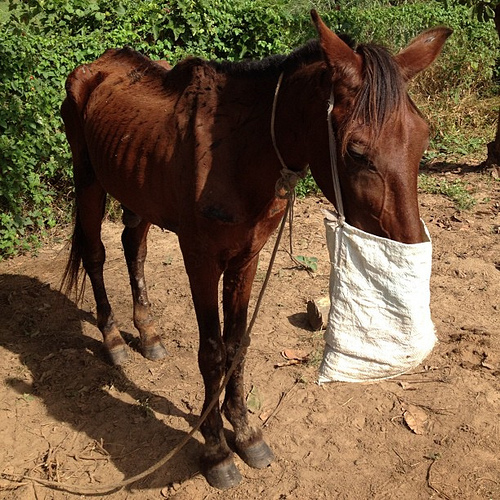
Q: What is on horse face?
A: White feed bag.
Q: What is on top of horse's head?
A: Brown hair.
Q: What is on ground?
A: Dirt.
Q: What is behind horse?
A: Brown tail.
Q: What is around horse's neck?
A: Rope.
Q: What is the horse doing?
A: Eating.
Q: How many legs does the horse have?
A: Four.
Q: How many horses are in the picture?
A: One.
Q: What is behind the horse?
A: Green foliage.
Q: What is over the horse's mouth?
A: A feed bag.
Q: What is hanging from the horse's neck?
A: A rope.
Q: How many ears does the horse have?
A: Two.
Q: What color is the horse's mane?
A: Black and brown.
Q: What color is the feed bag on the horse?
A: White.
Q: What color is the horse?
A: Brown.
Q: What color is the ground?
A: Brown.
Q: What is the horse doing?
A: Eating.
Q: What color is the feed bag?
A: White.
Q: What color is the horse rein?
A: Gray.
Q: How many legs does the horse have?
A: 4.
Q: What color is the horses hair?
A: Black.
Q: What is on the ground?
A: Dirt.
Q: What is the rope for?
A: To tie the horse.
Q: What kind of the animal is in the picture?
A: Horse.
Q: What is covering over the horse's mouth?
A: A bag.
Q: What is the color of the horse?
A: Brown.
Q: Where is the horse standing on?
A: On the dirt.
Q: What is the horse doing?
A: Eating.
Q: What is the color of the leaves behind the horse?
A: Green.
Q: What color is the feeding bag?
A: White.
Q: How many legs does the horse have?
A: Four.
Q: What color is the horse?
A: Brown.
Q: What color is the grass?
A: Green.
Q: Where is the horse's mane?
A: On it's back.